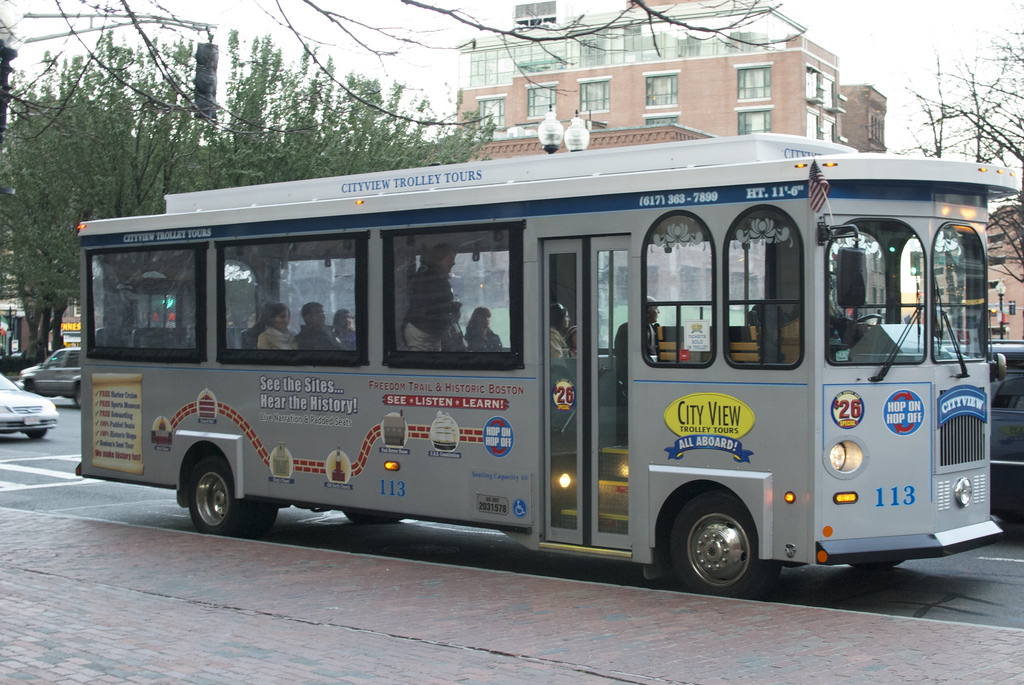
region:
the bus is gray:
[41, 116, 1019, 610]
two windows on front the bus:
[817, 205, 1002, 384]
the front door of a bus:
[524, 217, 654, 572]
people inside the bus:
[231, 270, 523, 363]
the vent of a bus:
[919, 377, 996, 475]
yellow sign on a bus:
[660, 379, 763, 456]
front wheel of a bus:
[641, 476, 778, 610]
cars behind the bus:
[0, 267, 178, 502]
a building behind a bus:
[433, 3, 921, 239]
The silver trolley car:
[67, 132, 1022, 588]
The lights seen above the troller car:
[531, 95, 598, 157]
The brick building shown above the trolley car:
[441, 3, 909, 158]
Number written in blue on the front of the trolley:
[867, 472, 921, 512]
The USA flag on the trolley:
[794, 156, 833, 226]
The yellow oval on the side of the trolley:
[658, 385, 761, 458]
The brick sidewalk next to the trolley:
[1, 500, 1022, 684]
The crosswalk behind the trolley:
[2, 443, 113, 500]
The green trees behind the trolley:
[0, 29, 509, 324]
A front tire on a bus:
[672, 502, 771, 601]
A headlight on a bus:
[823, 439, 866, 475]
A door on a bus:
[526, 227, 650, 545]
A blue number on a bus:
[877, 481, 916, 510]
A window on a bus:
[213, 240, 365, 351]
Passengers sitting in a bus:
[257, 300, 365, 346]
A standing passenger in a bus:
[397, 247, 464, 353]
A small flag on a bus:
[800, 155, 826, 207]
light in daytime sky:
[4, 1, 1019, 154]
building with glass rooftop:
[458, 1, 844, 96]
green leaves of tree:
[4, 38, 498, 349]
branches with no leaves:
[0, 0, 804, 119]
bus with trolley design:
[76, 134, 1019, 596]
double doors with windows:
[538, 235, 625, 548]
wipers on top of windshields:
[829, 219, 992, 382]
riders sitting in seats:
[244, 237, 510, 356]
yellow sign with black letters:
[659, 388, 758, 440]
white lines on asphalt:
[0, 452, 87, 494]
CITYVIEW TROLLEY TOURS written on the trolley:
[326, 154, 500, 205]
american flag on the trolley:
[806, 160, 842, 243]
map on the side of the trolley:
[150, 384, 528, 508]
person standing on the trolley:
[384, 217, 482, 353]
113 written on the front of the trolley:
[865, 473, 930, 524]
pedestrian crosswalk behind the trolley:
[0, 427, 91, 515]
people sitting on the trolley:
[251, 290, 364, 362]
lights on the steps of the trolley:
[546, 434, 643, 533]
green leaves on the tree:
[49, 133, 114, 188]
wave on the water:
[93, 30, 113, 97]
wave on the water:
[258, 109, 291, 155]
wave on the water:
[286, 140, 324, 170]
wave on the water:
[333, 87, 390, 161]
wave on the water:
[264, 134, 310, 191]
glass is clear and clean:
[387, 230, 518, 352]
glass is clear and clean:
[646, 217, 716, 363]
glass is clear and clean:
[728, 204, 808, 363]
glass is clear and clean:
[824, 219, 926, 362]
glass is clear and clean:
[938, 227, 990, 357]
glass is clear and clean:
[589, 245, 629, 533]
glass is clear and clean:
[549, 252, 579, 528]